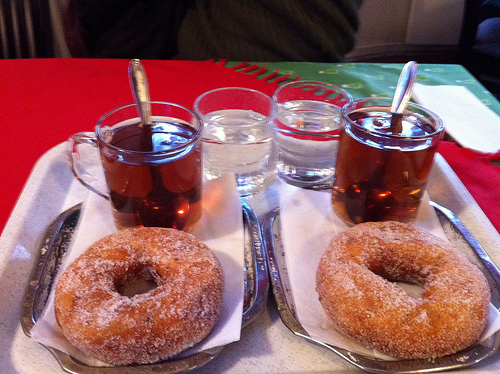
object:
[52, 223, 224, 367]
doughnut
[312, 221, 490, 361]
doughnut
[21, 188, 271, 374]
plate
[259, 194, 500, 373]
plate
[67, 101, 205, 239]
glass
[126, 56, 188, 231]
spoon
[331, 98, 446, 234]
glass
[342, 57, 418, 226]
spoon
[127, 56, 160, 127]
handle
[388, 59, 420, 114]
handle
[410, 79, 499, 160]
napkin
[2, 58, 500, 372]
table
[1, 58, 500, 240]
table cloth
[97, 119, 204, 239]
tea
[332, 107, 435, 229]
tea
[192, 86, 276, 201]
glass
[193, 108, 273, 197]
water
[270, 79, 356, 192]
glass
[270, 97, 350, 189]
water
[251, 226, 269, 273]
writing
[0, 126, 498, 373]
tray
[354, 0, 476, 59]
wall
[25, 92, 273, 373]
meal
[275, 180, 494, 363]
napkin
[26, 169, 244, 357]
napkin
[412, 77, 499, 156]
stack